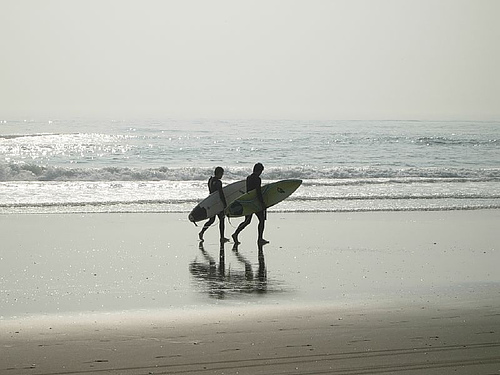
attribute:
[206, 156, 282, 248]
surfers — standing, walking, wet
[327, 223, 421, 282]
beach — sandy, sunny, wet, brown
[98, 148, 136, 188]
wave — crashing, white, blue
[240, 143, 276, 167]
water — blue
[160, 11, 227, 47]
sky — blue, sunny